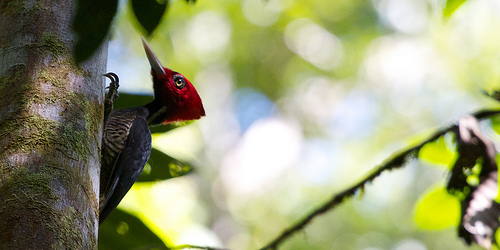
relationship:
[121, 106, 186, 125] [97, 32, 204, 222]
feathers on woodpecker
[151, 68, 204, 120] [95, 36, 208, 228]
head of a woodpecker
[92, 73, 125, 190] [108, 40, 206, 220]
claws of a bird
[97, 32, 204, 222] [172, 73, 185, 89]
woodpecker left eye